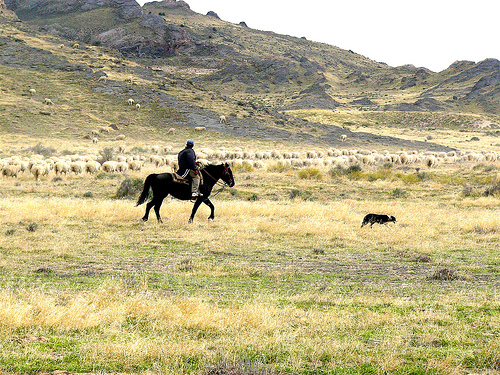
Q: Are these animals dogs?
A: No, they are horses and dogs.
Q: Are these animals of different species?
A: Yes, they are horses and dogs.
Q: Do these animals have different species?
A: Yes, they are horses and dogs.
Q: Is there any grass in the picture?
A: Yes, there is grass.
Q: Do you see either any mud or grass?
A: Yes, there is grass.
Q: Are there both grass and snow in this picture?
A: No, there is grass but no snow.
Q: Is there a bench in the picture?
A: No, there are no benches.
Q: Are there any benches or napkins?
A: No, there are no benches or napkins.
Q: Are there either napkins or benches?
A: No, there are no benches or napkins.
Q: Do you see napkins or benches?
A: No, there are no benches or napkins.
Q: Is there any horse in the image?
A: Yes, there is a horse.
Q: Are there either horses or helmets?
A: Yes, there is a horse.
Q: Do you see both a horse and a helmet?
A: No, there is a horse but no helmets.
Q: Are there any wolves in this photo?
A: No, there are no wolves.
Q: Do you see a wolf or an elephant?
A: No, there are no wolves or elephants.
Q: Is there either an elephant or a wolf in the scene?
A: No, there are no wolves or elephants.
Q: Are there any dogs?
A: Yes, there is a dog.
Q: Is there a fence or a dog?
A: Yes, there is a dog.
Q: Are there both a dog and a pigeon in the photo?
A: No, there is a dog but no pigeons.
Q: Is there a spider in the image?
A: No, there are no spiders.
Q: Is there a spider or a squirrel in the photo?
A: No, there are no spiders or squirrels.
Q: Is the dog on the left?
A: No, the dog is on the right of the image.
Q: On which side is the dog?
A: The dog is on the right of the image.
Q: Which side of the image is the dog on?
A: The dog is on the right of the image.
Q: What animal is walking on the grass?
A: The dog is walking on the grass.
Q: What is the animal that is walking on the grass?
A: The animal is a dog.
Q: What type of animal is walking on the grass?
A: The animal is a dog.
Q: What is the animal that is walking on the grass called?
A: The animal is a dog.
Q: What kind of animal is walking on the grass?
A: The animal is a dog.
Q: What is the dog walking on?
A: The dog is walking on the grass.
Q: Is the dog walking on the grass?
A: Yes, the dog is walking on the grass.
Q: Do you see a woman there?
A: No, there are no women.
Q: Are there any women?
A: No, there are no women.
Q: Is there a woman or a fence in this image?
A: No, there are no women or fences.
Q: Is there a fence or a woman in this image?
A: No, there are no women or fences.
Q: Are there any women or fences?
A: No, there are no women or fences.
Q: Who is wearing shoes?
A: The man is wearing shoes.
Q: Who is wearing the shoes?
A: The man is wearing shoes.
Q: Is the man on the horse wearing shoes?
A: Yes, the man is wearing shoes.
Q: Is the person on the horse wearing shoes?
A: Yes, the man is wearing shoes.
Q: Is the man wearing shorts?
A: No, the man is wearing shoes.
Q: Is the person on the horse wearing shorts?
A: No, the man is wearing shoes.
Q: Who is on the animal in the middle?
A: The man is on the horse.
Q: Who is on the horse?
A: The man is on the horse.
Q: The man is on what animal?
A: The man is on the horse.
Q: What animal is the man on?
A: The man is on the horse.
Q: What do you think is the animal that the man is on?
A: The animal is a horse.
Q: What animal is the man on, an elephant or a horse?
A: The man is on a horse.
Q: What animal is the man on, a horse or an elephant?
A: The man is on a horse.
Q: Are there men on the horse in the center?
A: Yes, there is a man on the horse.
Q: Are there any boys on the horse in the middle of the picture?
A: No, there is a man on the horse.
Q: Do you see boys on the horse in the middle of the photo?
A: No, there is a man on the horse.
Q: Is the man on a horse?
A: Yes, the man is on a horse.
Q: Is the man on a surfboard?
A: No, the man is on a horse.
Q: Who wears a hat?
A: The man wears a hat.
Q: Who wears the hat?
A: The man wears a hat.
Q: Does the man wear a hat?
A: Yes, the man wears a hat.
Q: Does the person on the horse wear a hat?
A: Yes, the man wears a hat.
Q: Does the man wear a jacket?
A: No, the man wears a hat.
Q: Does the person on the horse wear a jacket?
A: No, the man wears a hat.